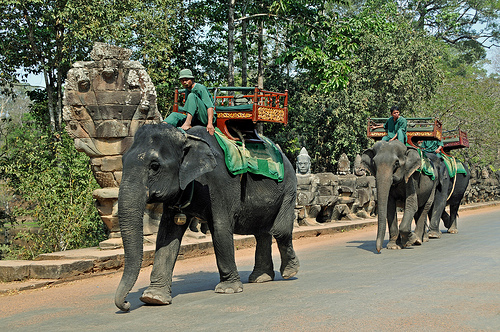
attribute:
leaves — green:
[2, 5, 493, 157]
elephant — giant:
[99, 117, 307, 314]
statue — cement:
[55, 36, 166, 246]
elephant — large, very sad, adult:
[111, 119, 301, 309]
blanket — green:
[211, 126, 286, 182]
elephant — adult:
[360, 138, 434, 253]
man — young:
[173, 60, 241, 132]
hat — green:
[174, 57, 226, 87]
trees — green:
[3, 118, 114, 259]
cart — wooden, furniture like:
[173, 82, 292, 128]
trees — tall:
[19, 3, 496, 158]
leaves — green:
[270, 20, 310, 52]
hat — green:
[176, 68, 195, 79]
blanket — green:
[206, 122, 288, 182]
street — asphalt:
[0, 202, 500, 327]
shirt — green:
[384, 114, 409, 138]